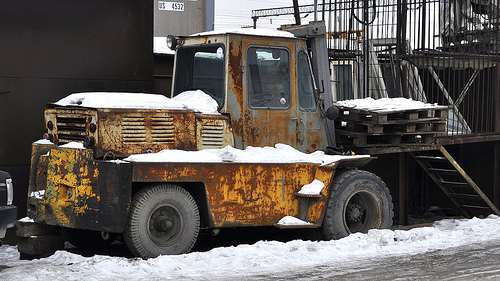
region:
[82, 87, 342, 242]
A truck on snow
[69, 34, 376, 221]
An old truck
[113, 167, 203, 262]
wheel of a truck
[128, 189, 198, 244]
Tire on the wheel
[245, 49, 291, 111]
window on the truck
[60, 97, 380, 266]
A truck in the photo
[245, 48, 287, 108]
the side window of an old tractor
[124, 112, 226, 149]
three vents on the side of a tractor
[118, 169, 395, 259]
two large tractor tires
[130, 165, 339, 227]
rust along the side of a tractor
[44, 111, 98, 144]
the front grill of a tractor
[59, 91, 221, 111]
snow on the hood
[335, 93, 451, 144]
pallets on the back of a tractor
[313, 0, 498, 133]
metal bars on a gate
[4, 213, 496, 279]
an ice and snow covered street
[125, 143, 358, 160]
snow piles on the step of a tractor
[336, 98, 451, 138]
Wooden pallets on a loader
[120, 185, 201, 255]
A tire on a loader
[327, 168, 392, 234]
A tire on a loader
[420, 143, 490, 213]
A ladder under a dock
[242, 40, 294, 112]
A window on a loader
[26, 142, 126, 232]
Metal bumper on a loader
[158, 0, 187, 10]
White tag with a number on it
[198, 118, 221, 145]
Vent panel on a loader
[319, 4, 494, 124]
Black metal fence behind a loader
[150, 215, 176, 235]
Rim on a loader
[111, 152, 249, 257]
wheel of the vehicle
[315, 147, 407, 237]
back tire of vehicle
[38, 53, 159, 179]
front of the vehicle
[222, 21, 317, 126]
side window of the vehicle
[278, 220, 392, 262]
snow on the ground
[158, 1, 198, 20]
number on the building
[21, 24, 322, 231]
yellow vehicle on ground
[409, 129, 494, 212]
ladder on the snow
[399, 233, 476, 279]
street next to the snow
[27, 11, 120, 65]
wall next to the vehicle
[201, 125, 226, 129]
vent on a forklift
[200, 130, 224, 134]
vent on a forklift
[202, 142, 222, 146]
vent on a forklift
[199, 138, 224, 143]
vent on a forklift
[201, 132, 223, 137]
vent on a forklift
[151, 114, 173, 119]
vent on a forklift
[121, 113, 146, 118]
vent on a forklift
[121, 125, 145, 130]
vent on a forklift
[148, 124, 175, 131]
vent on a forklift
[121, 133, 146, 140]
vent on a forklift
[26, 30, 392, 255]
a rust fork lift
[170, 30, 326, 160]
the drivers cab area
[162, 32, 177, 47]
a flood light on the roof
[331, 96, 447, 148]
a pile of pallets